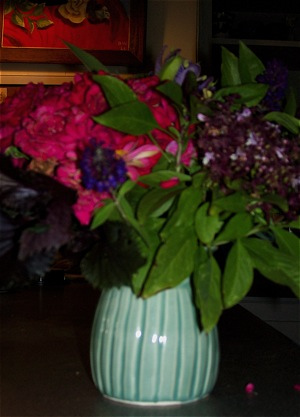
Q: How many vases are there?
A: One.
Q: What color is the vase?
A: Green.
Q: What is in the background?
A: A picture.